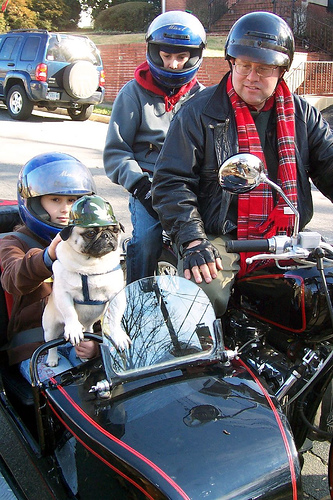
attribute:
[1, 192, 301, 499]
sidecar — black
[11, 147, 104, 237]
helmet — blue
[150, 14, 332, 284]
man — driving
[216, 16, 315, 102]
helmet — black, blue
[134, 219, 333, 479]
motorcycle — silver, red, black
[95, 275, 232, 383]
windshield — curved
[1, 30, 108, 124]
suv — parked, blue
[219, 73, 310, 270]
scarf — red, plaid, white, green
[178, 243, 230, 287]
gloves — leather, black, fingerless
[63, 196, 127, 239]
helmet — camoflage, camoflauge, green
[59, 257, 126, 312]
harness — blue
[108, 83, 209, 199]
sweater — grey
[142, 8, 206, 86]
helmet — blue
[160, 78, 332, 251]
jacket — black, leather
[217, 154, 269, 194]
rearview mirror — chrome, silver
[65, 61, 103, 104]
case — leather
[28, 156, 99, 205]
visor — clear